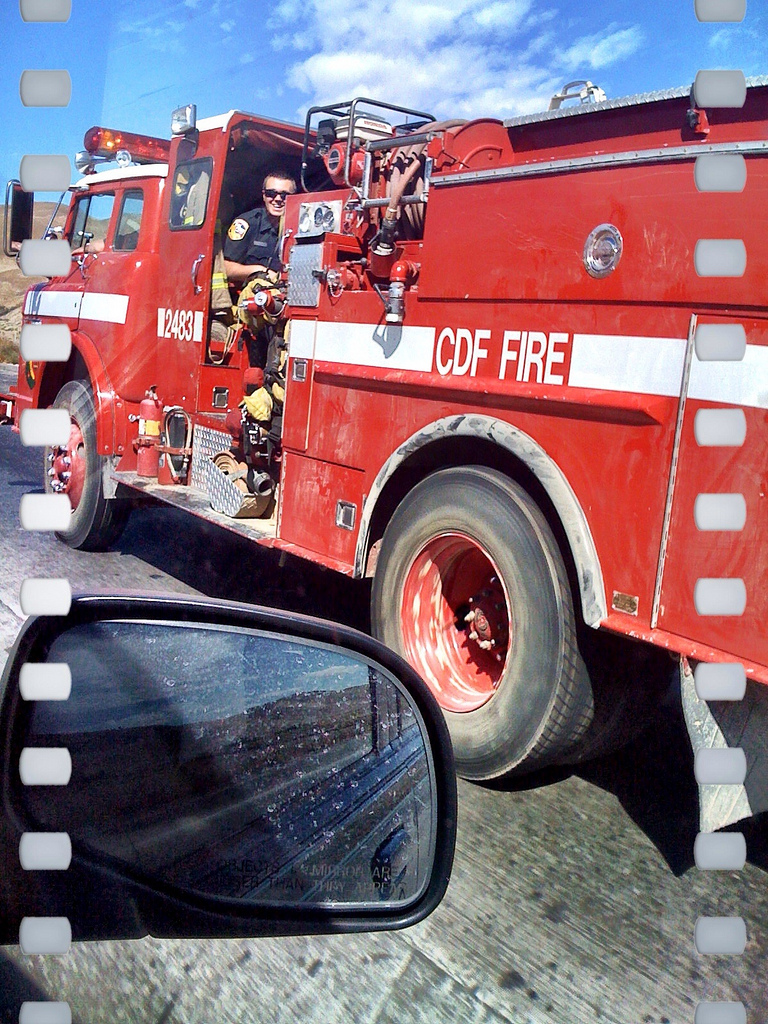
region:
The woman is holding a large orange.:
[528, 953, 548, 978]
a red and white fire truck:
[15, 115, 762, 682]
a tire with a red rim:
[378, 462, 630, 777]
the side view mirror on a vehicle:
[6, 590, 462, 944]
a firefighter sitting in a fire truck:
[215, 148, 314, 349]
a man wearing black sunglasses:
[261, 177, 299, 216]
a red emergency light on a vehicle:
[83, 121, 180, 172]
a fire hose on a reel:
[359, 118, 504, 257]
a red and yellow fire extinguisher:
[136, 386, 160, 480]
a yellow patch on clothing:
[228, 217, 252, 243]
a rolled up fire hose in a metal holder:
[201, 453, 277, 521]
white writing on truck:
[432, 327, 569, 385]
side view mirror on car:
[15, 581, 467, 968]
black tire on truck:
[373, 469, 616, 790]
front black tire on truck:
[22, 379, 119, 556]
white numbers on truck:
[154, 307, 209, 356]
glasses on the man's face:
[259, 187, 297, 208]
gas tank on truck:
[571, 225, 632, 285]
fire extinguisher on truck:
[121, 379, 175, 487]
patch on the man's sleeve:
[218, 212, 252, 244]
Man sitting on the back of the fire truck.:
[219, 168, 284, 323]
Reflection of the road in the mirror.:
[125, 679, 359, 874]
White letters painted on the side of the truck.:
[427, 321, 580, 386]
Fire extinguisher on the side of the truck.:
[109, 357, 177, 497]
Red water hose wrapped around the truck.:
[368, 128, 422, 231]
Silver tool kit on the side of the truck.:
[177, 411, 253, 511]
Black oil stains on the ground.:
[502, 967, 580, 1010]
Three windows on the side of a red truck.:
[43, 144, 238, 251]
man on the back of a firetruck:
[210, 163, 303, 461]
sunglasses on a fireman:
[258, 185, 293, 203]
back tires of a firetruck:
[360, 450, 658, 787]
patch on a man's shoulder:
[224, 217, 255, 248]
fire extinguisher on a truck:
[132, 388, 164, 488]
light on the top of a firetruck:
[76, 127, 182, 163]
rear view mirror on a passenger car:
[2, 583, 466, 946]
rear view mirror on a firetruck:
[2, 175, 41, 262]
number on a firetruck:
[159, 310, 194, 340]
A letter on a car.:
[518, 329, 550, 384]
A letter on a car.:
[511, 326, 531, 381]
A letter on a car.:
[469, 322, 495, 382]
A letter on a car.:
[444, 328, 471, 382]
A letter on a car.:
[431, 322, 462, 376]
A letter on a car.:
[179, 305, 195, 341]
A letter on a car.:
[170, 303, 180, 337]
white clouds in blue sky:
[4, 0, 765, 216]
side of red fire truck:
[4, 74, 766, 789]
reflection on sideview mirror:
[2, 589, 456, 942]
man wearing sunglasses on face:
[262, 170, 299, 219]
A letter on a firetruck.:
[545, 325, 575, 387]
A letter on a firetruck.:
[519, 324, 547, 384]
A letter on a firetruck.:
[515, 328, 531, 379]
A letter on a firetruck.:
[494, 326, 520, 381]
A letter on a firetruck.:
[466, 324, 493, 381]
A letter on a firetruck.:
[452, 324, 473, 378]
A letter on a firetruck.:
[436, 325, 453, 373]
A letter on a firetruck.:
[184, 307, 191, 342]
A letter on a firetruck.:
[177, 311, 187, 337]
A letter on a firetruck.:
[170, 310, 180, 334]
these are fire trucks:
[44, 132, 740, 880]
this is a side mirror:
[121, 614, 378, 928]